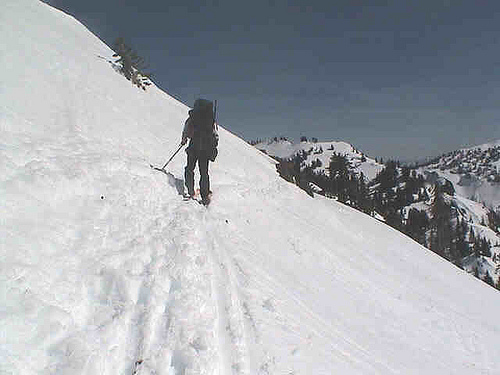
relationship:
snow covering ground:
[0, 0, 500, 375] [11, 207, 322, 369]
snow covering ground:
[0, 0, 500, 375] [1, 211, 355, 373]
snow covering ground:
[0, 0, 500, 375] [6, 2, 497, 372]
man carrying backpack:
[166, 96, 256, 207] [168, 90, 218, 121]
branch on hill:
[109, 32, 156, 92] [1, 0, 496, 371]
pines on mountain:
[285, 154, 487, 266] [248, 137, 497, 287]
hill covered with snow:
[1, 0, 496, 371] [0, 0, 498, 373]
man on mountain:
[179, 109, 220, 206] [0, 3, 498, 372]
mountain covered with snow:
[0, 0, 500, 375] [249, 135, 386, 177]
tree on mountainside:
[109, 33, 159, 95] [0, 0, 499, 373]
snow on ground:
[0, 0, 498, 373] [6, 2, 497, 372]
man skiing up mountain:
[179, 109, 220, 206] [0, 3, 498, 372]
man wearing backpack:
[179, 109, 220, 206] [166, 119, 234, 159]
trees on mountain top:
[246, 136, 499, 291] [251, 136, 498, 292]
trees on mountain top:
[281, 145, 479, 267] [260, 130, 499, 285]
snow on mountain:
[0, 0, 500, 375] [250, 119, 495, 296]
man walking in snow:
[179, 109, 220, 206] [26, 17, 491, 373]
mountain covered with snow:
[0, 0, 500, 375] [15, 15, 462, 367]